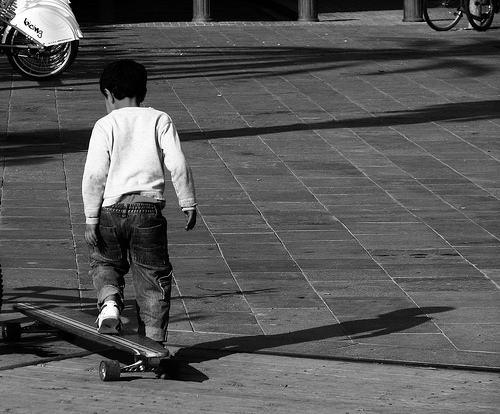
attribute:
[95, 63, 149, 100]
hair — dark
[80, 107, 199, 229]
sweater — long sleeved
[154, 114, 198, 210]
sleeve shirt — long sleeved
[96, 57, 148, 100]
hair — dark, jet black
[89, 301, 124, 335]
tennis shoe — white 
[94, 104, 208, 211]
sweater — white 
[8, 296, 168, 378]
skateboard — wooden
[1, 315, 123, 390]
wheels — black